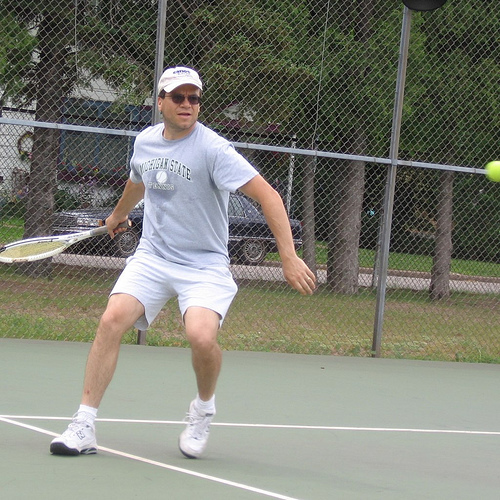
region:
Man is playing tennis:
[0, 64, 498, 460]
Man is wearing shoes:
[47, 407, 213, 464]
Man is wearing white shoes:
[48, 400, 218, 458]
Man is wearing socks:
[72, 390, 217, 421]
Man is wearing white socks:
[77, 393, 218, 424]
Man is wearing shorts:
[112, 236, 245, 323]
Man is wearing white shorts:
[105, 244, 239, 329]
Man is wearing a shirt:
[119, 115, 265, 267]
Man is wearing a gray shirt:
[123, 120, 260, 268]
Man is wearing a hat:
[155, 61, 205, 98]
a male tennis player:
[48, 65, 318, 457]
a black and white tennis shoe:
[48, 421, 97, 454]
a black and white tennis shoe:
[179, 398, 216, 458]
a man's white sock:
[76, 404, 97, 424]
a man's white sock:
[194, 393, 214, 410]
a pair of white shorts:
[102, 249, 237, 330]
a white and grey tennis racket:
[0, 216, 131, 263]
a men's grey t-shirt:
[128, 122, 256, 269]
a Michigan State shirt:
[127, 121, 258, 268]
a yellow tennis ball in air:
[483, 158, 498, 178]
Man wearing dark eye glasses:
[36, 65, 321, 461]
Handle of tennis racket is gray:
[86, 215, 126, 237]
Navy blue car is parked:
[50, 185, 301, 267]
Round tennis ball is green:
[482, 160, 497, 180]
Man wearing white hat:
[45, 65, 320, 456]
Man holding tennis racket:
[35, 62, 317, 457]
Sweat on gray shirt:
[140, 162, 177, 227]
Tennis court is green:
[0, 336, 496, 496]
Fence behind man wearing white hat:
[0, 0, 498, 367]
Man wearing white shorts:
[27, 67, 319, 458]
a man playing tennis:
[1, 62, 317, 459]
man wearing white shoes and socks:
[51, 394, 217, 461]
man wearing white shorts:
[112, 246, 236, 323]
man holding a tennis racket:
[1, 217, 132, 264]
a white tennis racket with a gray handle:
[1, 219, 133, 262]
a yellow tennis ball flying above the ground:
[483, 157, 499, 183]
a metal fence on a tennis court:
[1, 0, 498, 358]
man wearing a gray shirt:
[130, 120, 259, 268]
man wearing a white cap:
[153, 64, 203, 96]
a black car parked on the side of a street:
[51, 187, 304, 267]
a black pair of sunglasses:
[168, 92, 200, 104]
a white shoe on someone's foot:
[48, 418, 98, 455]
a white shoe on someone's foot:
[178, 400, 217, 459]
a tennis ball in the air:
[483, 159, 499, 181]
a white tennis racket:
[0, 217, 135, 263]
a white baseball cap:
[157, 65, 202, 94]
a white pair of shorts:
[108, 253, 238, 328]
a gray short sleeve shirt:
[128, 120, 260, 272]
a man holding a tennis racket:
[1, 65, 316, 458]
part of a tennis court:
[3, 336, 498, 496]